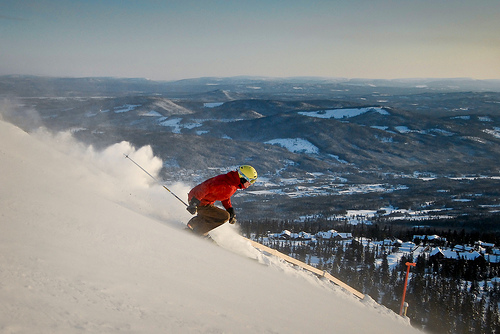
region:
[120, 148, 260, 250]
Man skiing on the slope.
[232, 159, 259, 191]
Yellow helmet on the man.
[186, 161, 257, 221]
Red jacket on the man.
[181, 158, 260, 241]
Brown pants on the man.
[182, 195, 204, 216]
Black glove on the hand.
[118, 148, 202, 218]
Ski pole in the hand.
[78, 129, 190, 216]
Flying snow in the air.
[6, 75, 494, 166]
Hills in the background.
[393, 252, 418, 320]
Red pole in the ground.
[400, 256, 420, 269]
Red arrow on the pole.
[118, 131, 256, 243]
the person is skiing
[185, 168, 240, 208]
the jacket is red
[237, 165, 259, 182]
the helmet is yellow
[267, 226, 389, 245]
the buildings look tiny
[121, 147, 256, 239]
the person has ski poles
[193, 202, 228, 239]
the person has brown pants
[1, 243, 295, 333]
the snow is on the ground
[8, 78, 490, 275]
the person is above the buildings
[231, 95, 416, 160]
the mountains have snow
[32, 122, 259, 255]
the snow is billowing behind the person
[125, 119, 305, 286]
the woman is skiing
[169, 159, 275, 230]
the jacket is red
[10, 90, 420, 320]
a skier going down the hill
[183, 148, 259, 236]
skier is crouched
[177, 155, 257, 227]
skier wearing a helmet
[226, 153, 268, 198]
the helmet is yellow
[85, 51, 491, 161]
mountains with patches of snow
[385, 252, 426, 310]
a red pole on left side of snow track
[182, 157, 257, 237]
skier has black pants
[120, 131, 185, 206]
a snow pole on back skier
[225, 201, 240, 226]
a glove on left hand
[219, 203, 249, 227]
a glove on left hand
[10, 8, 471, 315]
A person is skiing down a mountain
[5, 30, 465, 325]
The person is skiing in the snow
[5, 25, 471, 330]
The person is on a steep hill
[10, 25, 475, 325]
The person is an experienced skier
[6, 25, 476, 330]
The person is a ski instructor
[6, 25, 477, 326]
A person is enjoying the mountain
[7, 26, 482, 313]
A person is having great fun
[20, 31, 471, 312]
The person is wearing a hat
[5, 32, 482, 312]
The person is wearing a red coat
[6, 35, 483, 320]
The person is skiing very fast